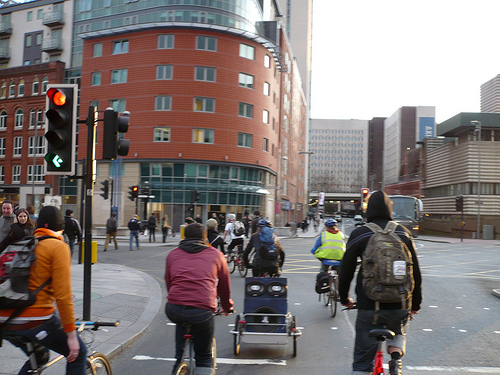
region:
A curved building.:
[72, 0, 298, 239]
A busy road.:
[0, 68, 424, 374]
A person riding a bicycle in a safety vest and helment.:
[312, 219, 345, 321]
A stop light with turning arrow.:
[41, 84, 77, 189]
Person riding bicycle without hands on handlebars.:
[4, 202, 134, 373]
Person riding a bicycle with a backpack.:
[352, 189, 426, 374]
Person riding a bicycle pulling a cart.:
[231, 213, 307, 366]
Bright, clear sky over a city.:
[314, 0, 497, 192]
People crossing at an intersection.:
[84, 197, 178, 262]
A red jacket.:
[162, 241, 232, 310]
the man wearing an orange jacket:
[0, 203, 87, 373]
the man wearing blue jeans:
[1, 205, 86, 374]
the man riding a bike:
[0, 204, 87, 374]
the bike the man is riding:
[0, 318, 118, 373]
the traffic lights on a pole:
[42, 82, 128, 319]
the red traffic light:
[52, 89, 65, 104]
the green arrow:
[52, 155, 62, 167]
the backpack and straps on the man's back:
[0, 233, 57, 347]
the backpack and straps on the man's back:
[361, 220, 413, 325]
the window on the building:
[194, 65, 216, 82]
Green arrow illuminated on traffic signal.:
[47, 148, 103, 186]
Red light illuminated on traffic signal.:
[46, 89, 78, 119]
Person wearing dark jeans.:
[165, 311, 235, 350]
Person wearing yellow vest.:
[318, 233, 361, 270]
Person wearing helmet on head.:
[317, 217, 337, 224]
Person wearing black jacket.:
[343, 210, 428, 332]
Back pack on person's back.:
[350, 232, 427, 298]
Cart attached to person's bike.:
[235, 269, 296, 366]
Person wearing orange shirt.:
[36, 251, 64, 279]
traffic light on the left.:
[44, 83, 75, 175]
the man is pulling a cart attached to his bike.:
[236, 275, 297, 356]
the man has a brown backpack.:
[363, 222, 413, 312]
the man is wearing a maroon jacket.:
[166, 241, 223, 311]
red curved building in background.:
[84, 35, 305, 227]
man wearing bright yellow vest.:
[321, 228, 343, 258]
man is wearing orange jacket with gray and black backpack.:
[0, 228, 72, 323]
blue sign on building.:
[417, 114, 434, 147]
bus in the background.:
[381, 193, 421, 238]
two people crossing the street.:
[105, 213, 141, 250]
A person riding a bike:
[357, 201, 414, 371]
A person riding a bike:
[312, 205, 347, 297]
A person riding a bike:
[245, 216, 285, 278]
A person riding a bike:
[217, 216, 249, 258]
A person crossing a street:
[100, 209, 121, 240]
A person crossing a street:
[158, 213, 172, 241]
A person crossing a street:
[143, 209, 157, 247]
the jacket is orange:
[0, 228, 75, 332]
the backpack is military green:
[358, 220, 415, 327]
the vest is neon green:
[313, 229, 345, 261]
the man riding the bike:
[163, 221, 235, 373]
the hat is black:
[36, 205, 62, 231]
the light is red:
[51, 92, 66, 105]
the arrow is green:
[51, 153, 63, 166]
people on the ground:
[112, 155, 447, 336]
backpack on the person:
[335, 204, 425, 304]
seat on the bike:
[344, 312, 408, 359]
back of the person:
[141, 245, 243, 299]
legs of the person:
[146, 311, 223, 366]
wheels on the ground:
[200, 288, 320, 366]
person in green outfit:
[298, 213, 353, 273]